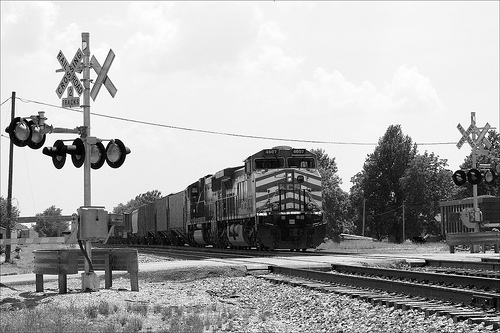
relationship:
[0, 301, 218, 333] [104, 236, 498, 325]
grass by railroad tracks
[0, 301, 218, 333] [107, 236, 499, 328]
grass by railroad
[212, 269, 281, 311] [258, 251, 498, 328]
rocks by tracks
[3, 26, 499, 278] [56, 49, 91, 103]
railroad crossing has sign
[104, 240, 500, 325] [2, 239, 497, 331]
railroad tracks on ground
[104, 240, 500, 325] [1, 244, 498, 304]
railroad tracks on road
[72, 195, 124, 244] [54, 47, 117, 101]
box on crossingsign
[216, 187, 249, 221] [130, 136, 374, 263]
railings on side of train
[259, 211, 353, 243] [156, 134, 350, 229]
guard on train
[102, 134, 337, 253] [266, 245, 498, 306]
train in tracks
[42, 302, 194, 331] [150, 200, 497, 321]
grass near railroad tracks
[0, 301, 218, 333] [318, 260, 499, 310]
grass near railroad tracks